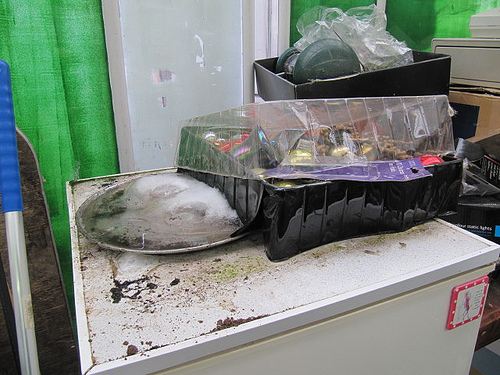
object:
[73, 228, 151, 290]
plate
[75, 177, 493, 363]
board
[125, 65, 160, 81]
plate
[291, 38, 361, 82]
plate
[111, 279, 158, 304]
dirt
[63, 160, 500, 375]
white surface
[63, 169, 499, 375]
freezer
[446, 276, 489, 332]
magnet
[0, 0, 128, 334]
curtain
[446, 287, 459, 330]
edge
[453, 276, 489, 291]
edge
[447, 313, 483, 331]
edge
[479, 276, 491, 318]
edge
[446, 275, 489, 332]
board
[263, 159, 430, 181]
purple plate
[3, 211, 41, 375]
silver pole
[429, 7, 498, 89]
register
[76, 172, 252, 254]
mold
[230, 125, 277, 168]
bell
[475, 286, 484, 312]
writing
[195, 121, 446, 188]
items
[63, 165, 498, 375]
table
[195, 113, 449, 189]
trash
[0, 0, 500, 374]
room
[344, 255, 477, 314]
edge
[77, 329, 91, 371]
part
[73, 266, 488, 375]
drawer